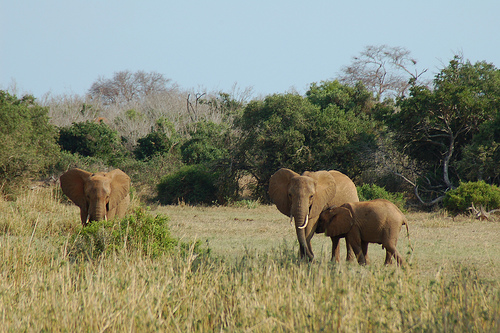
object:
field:
[0, 204, 500, 333]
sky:
[0, 0, 500, 104]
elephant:
[59, 167, 136, 226]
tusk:
[85, 215, 91, 226]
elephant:
[315, 199, 415, 272]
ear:
[61, 168, 87, 208]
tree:
[57, 120, 114, 159]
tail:
[401, 218, 414, 253]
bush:
[445, 179, 500, 220]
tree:
[81, 70, 186, 144]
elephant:
[268, 168, 360, 264]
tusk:
[296, 216, 310, 230]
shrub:
[50, 208, 179, 262]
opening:
[138, 200, 298, 263]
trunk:
[292, 205, 314, 262]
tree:
[392, 54, 500, 209]